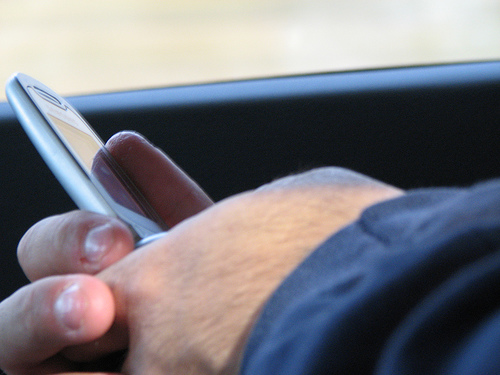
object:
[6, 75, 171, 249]
cellphone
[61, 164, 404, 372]
hand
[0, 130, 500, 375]
man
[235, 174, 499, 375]
sleeve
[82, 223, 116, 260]
fingernails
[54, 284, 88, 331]
fingernails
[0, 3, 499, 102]
window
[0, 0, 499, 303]
car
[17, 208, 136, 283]
finger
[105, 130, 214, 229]
finger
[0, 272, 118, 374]
finger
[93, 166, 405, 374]
hairy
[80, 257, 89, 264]
wound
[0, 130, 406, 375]
skin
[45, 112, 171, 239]
screen